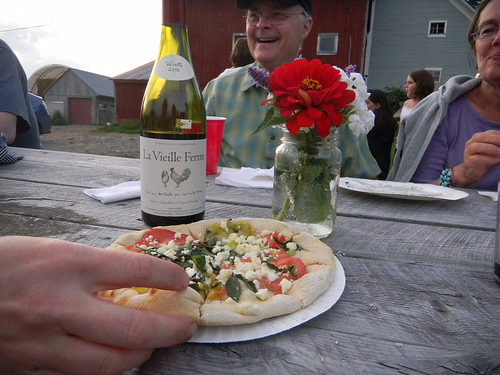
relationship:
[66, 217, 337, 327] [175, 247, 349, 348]
pizza over dish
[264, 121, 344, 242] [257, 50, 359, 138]
jar with daisy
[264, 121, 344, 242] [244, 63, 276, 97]
jar with flower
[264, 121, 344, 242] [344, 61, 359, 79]
jar with flower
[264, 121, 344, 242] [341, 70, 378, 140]
jar with flower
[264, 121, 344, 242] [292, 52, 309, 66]
jar with flower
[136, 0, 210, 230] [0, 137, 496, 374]
bottle on picnic table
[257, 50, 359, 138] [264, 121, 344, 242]
daisy in jar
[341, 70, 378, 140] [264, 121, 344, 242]
flower in jar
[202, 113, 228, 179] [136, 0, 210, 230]
glass behind bottle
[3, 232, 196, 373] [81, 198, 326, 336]
hand taking pizza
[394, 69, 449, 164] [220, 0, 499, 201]
girl sits behind couple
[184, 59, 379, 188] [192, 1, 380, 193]
shirt worn by man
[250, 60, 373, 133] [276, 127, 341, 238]
arrangement in jar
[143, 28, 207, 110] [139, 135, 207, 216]
bottle has label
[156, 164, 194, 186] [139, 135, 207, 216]
chickens on label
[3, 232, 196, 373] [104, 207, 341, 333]
hand reaching for pizza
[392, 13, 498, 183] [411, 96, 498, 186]
woman has purple shirt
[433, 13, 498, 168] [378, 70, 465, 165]
woman has sweater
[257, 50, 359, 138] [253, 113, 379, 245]
daisy in jar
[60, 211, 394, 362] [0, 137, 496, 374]
pizza on a picnic table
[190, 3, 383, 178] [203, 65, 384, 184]
person wearing clothes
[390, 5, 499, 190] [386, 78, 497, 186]
person wearing clothes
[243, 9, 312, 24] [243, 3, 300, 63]
eyeglasses on face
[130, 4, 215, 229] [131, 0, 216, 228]
wine in bottle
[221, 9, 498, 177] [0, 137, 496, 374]
couple in picnic table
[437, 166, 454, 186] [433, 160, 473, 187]
flower medallion on woman's wrist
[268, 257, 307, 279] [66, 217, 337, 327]
tomato on pizza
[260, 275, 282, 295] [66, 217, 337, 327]
tomato on pizza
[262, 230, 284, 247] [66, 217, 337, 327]
tomato on pizza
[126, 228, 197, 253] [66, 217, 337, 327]
tomato on pizza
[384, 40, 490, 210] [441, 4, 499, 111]
girl behind woman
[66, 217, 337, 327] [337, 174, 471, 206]
pizza on plate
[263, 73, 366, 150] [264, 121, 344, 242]
daisy in jar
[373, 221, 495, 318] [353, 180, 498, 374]
wood grain on picnic table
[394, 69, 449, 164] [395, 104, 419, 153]
girl wears tank top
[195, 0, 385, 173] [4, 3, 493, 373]
man in photo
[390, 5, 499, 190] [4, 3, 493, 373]
person in photo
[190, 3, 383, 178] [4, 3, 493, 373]
person in photo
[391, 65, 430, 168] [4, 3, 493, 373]
person in photo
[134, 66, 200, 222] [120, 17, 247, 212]
wine in bottle